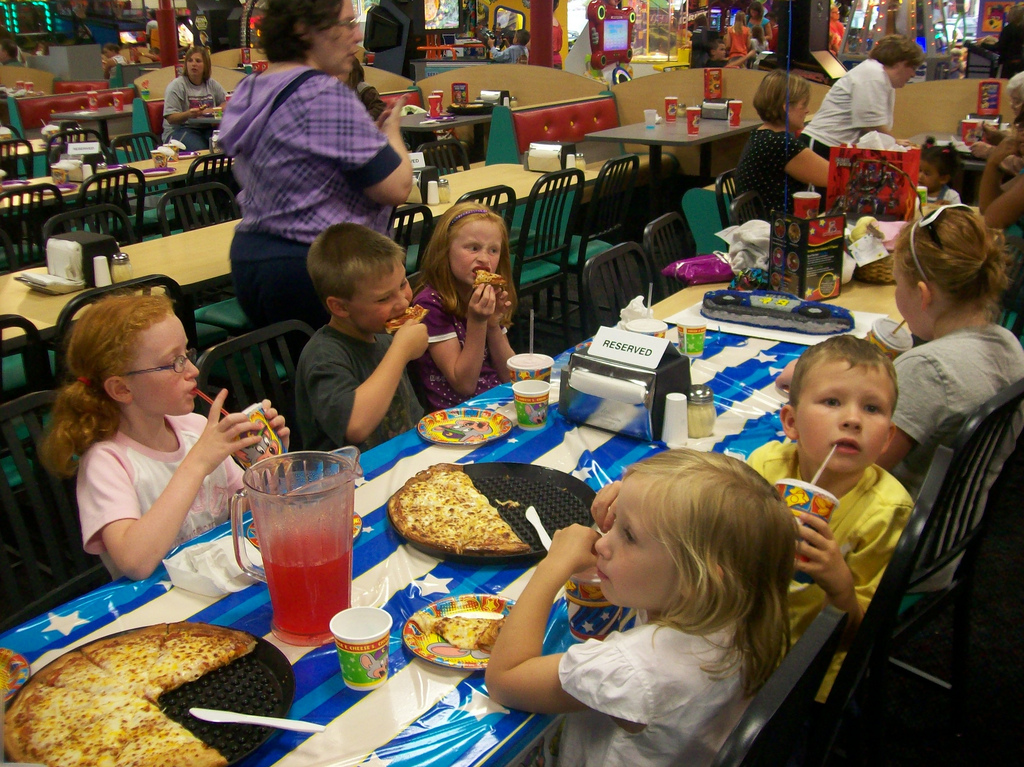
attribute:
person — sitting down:
[289, 219, 430, 440]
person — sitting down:
[410, 199, 534, 398]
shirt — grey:
[287, 323, 439, 451]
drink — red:
[259, 525, 353, 653]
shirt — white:
[549, 625, 753, 762]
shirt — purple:
[209, 65, 402, 243]